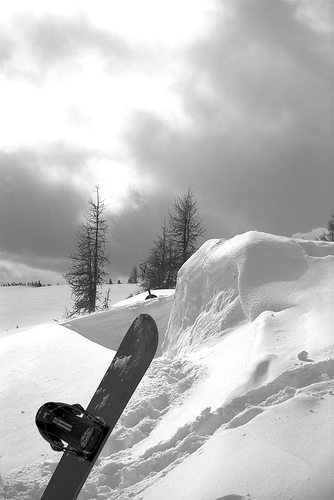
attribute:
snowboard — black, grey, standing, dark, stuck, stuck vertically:
[32, 309, 162, 494]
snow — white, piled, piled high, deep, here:
[8, 223, 333, 494]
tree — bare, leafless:
[66, 189, 124, 318]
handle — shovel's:
[142, 280, 164, 301]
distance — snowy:
[9, 223, 327, 341]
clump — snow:
[296, 341, 313, 362]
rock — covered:
[165, 212, 328, 349]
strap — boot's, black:
[36, 397, 107, 463]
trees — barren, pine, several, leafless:
[62, 186, 201, 319]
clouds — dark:
[12, 0, 333, 255]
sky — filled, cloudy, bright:
[8, 3, 330, 279]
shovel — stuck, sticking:
[142, 288, 160, 305]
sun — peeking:
[11, 0, 238, 217]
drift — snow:
[5, 222, 332, 486]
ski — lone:
[32, 310, 159, 496]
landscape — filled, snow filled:
[0, 217, 333, 491]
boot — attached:
[31, 397, 106, 465]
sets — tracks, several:
[3, 335, 332, 499]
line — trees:
[2, 264, 173, 289]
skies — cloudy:
[13, 1, 331, 270]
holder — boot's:
[34, 390, 107, 461]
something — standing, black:
[32, 308, 166, 496]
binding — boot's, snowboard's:
[36, 394, 111, 482]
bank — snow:
[4, 226, 322, 487]